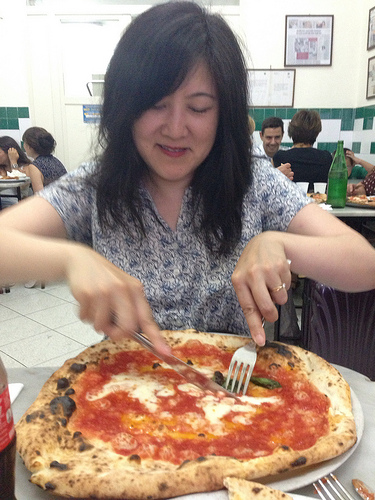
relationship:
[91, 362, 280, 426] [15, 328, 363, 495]
cheese on pizza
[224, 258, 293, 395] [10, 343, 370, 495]
fork on table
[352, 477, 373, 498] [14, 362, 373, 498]
knife on table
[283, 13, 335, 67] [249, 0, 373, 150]
picture on wall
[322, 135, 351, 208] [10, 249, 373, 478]
glass on table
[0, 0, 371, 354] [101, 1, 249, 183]
woman with head